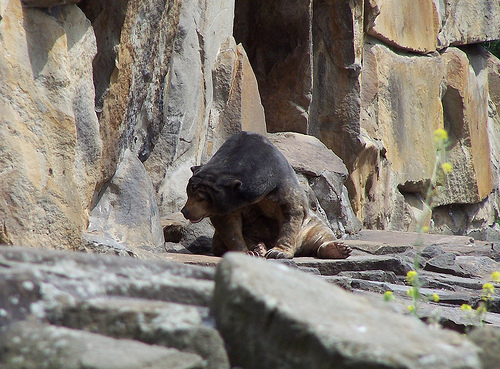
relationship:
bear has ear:
[157, 131, 353, 266] [188, 160, 244, 192]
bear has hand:
[157, 131, 353, 266] [208, 223, 302, 263]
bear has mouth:
[157, 131, 353, 266] [173, 205, 207, 225]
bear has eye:
[157, 131, 353, 266] [181, 187, 212, 204]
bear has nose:
[157, 131, 353, 266] [180, 204, 201, 225]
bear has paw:
[157, 131, 353, 266] [316, 243, 358, 255]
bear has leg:
[157, 131, 353, 266] [201, 219, 353, 260]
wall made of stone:
[51, 82, 150, 204] [40, 144, 89, 260]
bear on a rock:
[180, 129, 353, 259] [0, 2, 497, 367]